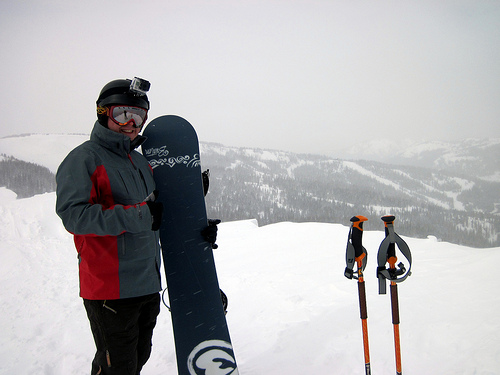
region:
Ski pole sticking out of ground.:
[361, 199, 417, 339]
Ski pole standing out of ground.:
[332, 215, 379, 337]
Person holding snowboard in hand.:
[148, 174, 221, 289]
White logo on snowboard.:
[186, 323, 225, 371]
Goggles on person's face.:
[112, 107, 169, 137]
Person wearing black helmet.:
[96, 69, 171, 125]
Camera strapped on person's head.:
[114, 69, 167, 109]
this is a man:
[58, 60, 163, 349]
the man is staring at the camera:
[58, 79, 160, 345]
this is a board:
[160, 187, 211, 244]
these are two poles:
[310, 214, 421, 372]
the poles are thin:
[323, 203, 418, 373]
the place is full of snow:
[254, 232, 333, 370]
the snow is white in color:
[274, 274, 336, 345]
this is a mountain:
[289, 160, 336, 196]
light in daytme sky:
[0, 3, 497, 140]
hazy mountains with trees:
[2, 132, 497, 222]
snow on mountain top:
[3, 131, 70, 193]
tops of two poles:
[342, 214, 416, 374]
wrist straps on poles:
[343, 224, 413, 286]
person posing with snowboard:
[56, 77, 238, 373]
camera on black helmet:
[99, 74, 149, 107]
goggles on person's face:
[99, 104, 149, 138]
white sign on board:
[147, 144, 201, 172]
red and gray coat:
[55, 122, 159, 300]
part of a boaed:
[192, 265, 209, 294]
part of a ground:
[302, 290, 318, 320]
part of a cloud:
[242, 74, 280, 113]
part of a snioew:
[286, 244, 321, 304]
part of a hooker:
[355, 305, 377, 338]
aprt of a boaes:
[193, 270, 216, 312]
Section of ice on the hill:
[327, 155, 401, 212]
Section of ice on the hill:
[404, 145, 479, 215]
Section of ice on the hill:
[244, 160, 327, 228]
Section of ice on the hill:
[3, 131, 47, 212]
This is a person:
[51, 67, 259, 372]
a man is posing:
[55, 76, 157, 374]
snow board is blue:
[142, 114, 239, 374]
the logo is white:
[187, 335, 237, 373]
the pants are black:
[80, 291, 162, 374]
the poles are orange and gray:
[344, 216, 411, 374]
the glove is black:
[205, 217, 220, 249]